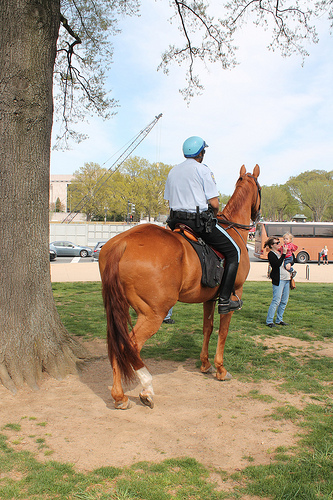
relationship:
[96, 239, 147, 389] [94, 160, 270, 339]
tail of horse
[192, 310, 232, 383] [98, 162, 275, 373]
legs of horse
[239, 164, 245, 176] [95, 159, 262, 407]
ear of horse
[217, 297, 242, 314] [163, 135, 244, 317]
foot of police officer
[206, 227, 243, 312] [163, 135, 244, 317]
leg of police officer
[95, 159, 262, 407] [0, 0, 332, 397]
horse near tree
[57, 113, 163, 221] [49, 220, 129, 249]
crane behind wall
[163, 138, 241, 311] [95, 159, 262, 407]
police officer on horse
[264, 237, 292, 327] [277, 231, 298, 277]
woman holding little girl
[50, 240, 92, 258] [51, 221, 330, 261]
car parked in lot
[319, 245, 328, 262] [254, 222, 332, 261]
person standing in front of bus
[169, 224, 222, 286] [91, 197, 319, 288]
saddle on horse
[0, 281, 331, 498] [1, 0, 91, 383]
green grass near tree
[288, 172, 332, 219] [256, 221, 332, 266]
tree behind bus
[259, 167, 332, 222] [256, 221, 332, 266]
tree behind bus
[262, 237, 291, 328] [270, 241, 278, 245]
woman wearing sunglasses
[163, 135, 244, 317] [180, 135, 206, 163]
police officer wearing helmet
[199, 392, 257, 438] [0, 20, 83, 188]
dirt area by tree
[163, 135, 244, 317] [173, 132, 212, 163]
police officer wearing helmet